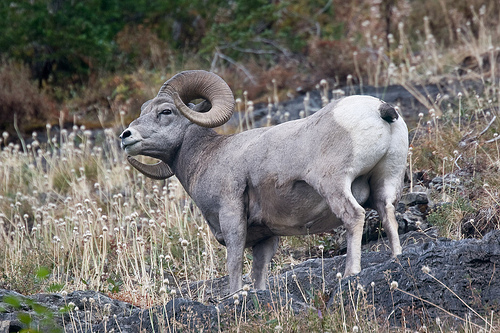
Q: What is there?
A: Animal.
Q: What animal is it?
A: Billy goat.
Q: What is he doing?
A: Watching.